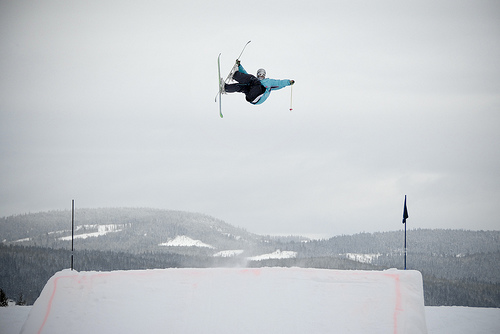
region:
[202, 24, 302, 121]
skier doing tricks in the snow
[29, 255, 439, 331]
a snow ramp for skiers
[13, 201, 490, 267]
mountains in the background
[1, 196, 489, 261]
mountains covered with trees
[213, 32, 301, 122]
man wearing blue jacket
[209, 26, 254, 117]
two skis in the air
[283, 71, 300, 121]
a snow pole on left hand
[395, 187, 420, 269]
a small pole with a flag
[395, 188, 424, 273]
a pole on side of snow ramp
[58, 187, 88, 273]
a stick on left side of ramp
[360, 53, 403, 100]
A white overcast sky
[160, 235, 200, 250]
Snow on the hill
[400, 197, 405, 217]
Black flag on a pole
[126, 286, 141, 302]
Small patch of snow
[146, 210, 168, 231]
Hills in the background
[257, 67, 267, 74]
Gray helmet of the skier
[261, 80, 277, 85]
Light blue sweater of the skier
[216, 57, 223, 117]
White ski of the skier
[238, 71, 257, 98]
Black pants of the skier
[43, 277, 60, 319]
Light red line on the snow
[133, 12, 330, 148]
this skier is doing a trick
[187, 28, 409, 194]
the skier is in mid air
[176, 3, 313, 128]
the skier is wearing a blue jacket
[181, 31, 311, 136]
the person is wearing black pants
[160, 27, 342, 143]
his skis appear to me in an odd position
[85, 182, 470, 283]
the mountains are dotted with snow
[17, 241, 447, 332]
the ski jump ramp appear steep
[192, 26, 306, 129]
the skier's helmet is silver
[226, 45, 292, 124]
the skier is wearing goggles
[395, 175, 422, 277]
a flag is to the right of the photo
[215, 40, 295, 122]
a person performing a jump on skis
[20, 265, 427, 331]
a ramp for performing ski jumps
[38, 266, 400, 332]
red lines on the ramp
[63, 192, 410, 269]
black poles behind the ramp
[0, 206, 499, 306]
hills behind the ramp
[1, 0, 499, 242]
a gray sky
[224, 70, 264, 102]
black pants on the skier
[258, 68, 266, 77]
white helmet and goggles on the skier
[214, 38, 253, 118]
white skis on the person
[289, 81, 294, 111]
ski pole in person's hand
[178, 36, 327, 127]
A skier up in the air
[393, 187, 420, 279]
a pole with a black flag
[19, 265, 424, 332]
orange line around ramp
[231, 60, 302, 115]
a light blue jacket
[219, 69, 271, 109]
black pants on a skier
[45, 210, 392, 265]
snow patches on the mountain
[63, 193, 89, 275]
a black pole without a flag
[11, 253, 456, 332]
a ramp covered in snow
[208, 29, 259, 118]
two skis on the feet of a skier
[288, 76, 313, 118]
one pole held out to the right